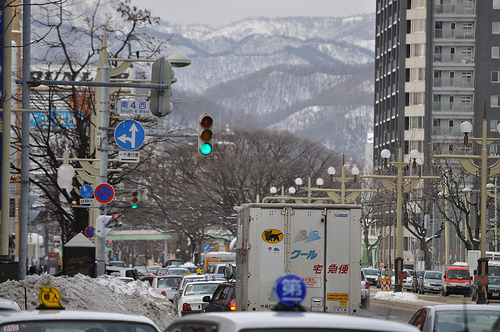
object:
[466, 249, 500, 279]
truck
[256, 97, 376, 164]
mountains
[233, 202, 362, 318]
truck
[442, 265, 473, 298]
van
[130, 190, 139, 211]
traffic light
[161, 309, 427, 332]
car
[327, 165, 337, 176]
light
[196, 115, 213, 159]
signal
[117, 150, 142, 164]
road sign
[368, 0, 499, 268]
building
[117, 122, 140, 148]
arrows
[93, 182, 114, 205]
sign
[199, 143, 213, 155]
green light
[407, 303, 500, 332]
car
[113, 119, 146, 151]
sign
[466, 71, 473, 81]
windows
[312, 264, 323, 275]
chinese writing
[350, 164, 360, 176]
light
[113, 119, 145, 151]
white arrows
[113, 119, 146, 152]
blue sign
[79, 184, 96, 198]
signs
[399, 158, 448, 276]
trees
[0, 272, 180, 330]
pile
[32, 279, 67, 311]
sign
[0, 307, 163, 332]
car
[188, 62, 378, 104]
mountain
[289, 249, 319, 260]
writing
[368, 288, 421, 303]
snow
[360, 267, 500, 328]
street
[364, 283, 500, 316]
roadway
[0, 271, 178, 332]
dirty snow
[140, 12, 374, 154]
snow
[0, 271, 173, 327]
snow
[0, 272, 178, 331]
snow mound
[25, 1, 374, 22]
sky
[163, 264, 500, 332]
road way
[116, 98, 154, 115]
sign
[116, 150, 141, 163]
sign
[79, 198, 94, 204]
sign